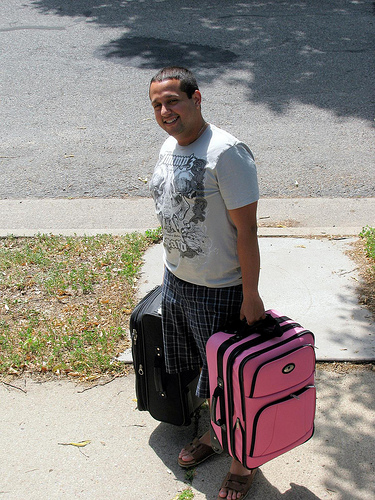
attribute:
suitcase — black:
[124, 277, 183, 434]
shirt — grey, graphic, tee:
[151, 131, 264, 294]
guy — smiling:
[141, 61, 265, 498]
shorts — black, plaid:
[151, 258, 259, 402]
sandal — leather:
[175, 437, 219, 468]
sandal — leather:
[215, 467, 256, 498]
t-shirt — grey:
[124, 115, 320, 278]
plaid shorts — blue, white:
[156, 264, 248, 377]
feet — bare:
[178, 429, 209, 460]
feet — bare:
[219, 461, 251, 499]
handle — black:
[239, 316, 283, 333]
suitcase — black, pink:
[210, 310, 325, 468]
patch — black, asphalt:
[94, 34, 249, 85]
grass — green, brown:
[37, 263, 97, 297]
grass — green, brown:
[121, 220, 142, 278]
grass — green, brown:
[50, 325, 112, 374]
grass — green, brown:
[3, 324, 45, 371]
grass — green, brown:
[7, 243, 50, 263]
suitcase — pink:
[212, 324, 322, 461]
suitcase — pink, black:
[199, 304, 317, 469]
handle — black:
[218, 316, 284, 337]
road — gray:
[1, 1, 373, 228]